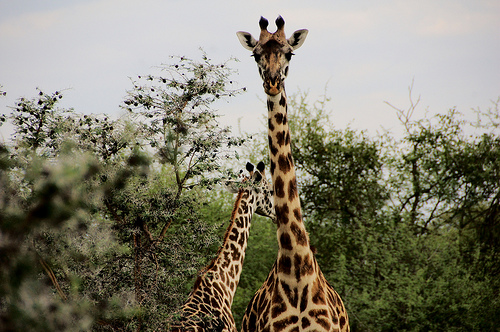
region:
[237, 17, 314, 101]
giraffe looking at camera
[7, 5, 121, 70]
clouds in the sky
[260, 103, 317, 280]
giraffe long skinny neck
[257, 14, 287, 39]
horns on giraffe head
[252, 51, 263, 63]
right giraffe eye looking at camera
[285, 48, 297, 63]
left giraffe eye looking at camera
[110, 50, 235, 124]
tip of brush high up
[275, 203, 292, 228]
brown spot on neck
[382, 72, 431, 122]
brush with no leaves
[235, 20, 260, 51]
right giraffe ear for hearing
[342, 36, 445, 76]
this is the sky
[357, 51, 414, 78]
the sky is blue in color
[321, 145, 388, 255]
this is a tree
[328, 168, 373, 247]
the leaves are green in color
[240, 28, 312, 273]
this is a giraffe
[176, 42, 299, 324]
the giraffes are two in number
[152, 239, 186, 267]
this is a thorn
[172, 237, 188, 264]
the thorns are white in color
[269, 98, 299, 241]
this is the neck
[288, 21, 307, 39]
this is the ear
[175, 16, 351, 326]
two giraffes standing near each other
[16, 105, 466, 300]
a patch of small trees and shrubs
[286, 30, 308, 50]
a giraffe's left ear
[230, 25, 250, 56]
a giraffe's right ear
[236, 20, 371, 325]
a giraffe looking straight forward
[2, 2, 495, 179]
a patch of gray cloudy sky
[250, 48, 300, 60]
a giraffe's long eyelashes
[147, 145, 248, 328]
a giraffe standing behind a larger giraffe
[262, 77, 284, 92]
a giraffe's flared nostrils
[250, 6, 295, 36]
a giraffe's small horns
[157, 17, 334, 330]
the giraffe are two in number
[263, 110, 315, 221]
this is the neck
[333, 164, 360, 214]
the leaves are green in color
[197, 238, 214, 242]
these are the thorns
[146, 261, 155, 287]
the thorns are white in color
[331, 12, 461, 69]
this is the sky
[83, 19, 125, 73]
the sky is blue in color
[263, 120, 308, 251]
the neck is long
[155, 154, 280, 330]
baby brown and white giraffe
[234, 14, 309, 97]
the head of an adult giraffe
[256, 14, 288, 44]
the horns on a giraffe's head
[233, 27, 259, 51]
giraffe ear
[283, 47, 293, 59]
giraffe eye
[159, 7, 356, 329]
adult and juvenile giraffe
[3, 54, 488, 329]
vegetation including tall trees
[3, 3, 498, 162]
gray sky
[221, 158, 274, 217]
head of a juvenile giraffe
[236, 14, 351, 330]
an adult giraffe poses for the camera